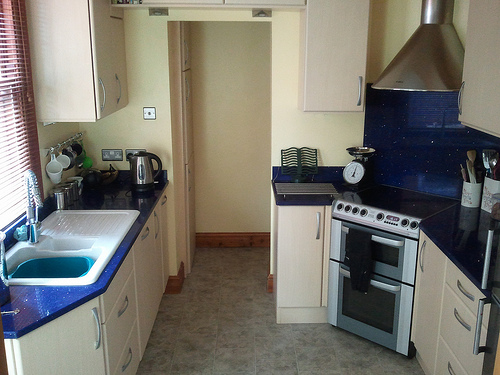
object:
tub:
[4, 255, 95, 279]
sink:
[0, 208, 143, 340]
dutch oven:
[328, 179, 464, 360]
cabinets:
[24, 0, 128, 127]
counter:
[0, 170, 169, 374]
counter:
[271, 165, 499, 375]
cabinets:
[300, 1, 372, 113]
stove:
[330, 185, 461, 240]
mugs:
[461, 176, 497, 213]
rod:
[43, 132, 84, 157]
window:
[0, 0, 47, 245]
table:
[275, 183, 339, 201]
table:
[419, 199, 500, 305]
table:
[0, 169, 168, 374]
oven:
[325, 181, 461, 358]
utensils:
[480, 149, 499, 182]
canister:
[461, 180, 482, 207]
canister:
[480, 175, 499, 215]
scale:
[343, 146, 376, 193]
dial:
[346, 146, 376, 158]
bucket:
[0, 241, 109, 285]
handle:
[315, 211, 320, 239]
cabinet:
[276, 205, 324, 307]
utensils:
[460, 151, 483, 185]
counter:
[410, 201, 499, 375]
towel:
[343, 228, 376, 295]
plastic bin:
[7, 256, 97, 278]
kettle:
[126, 150, 163, 195]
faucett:
[24, 169, 43, 244]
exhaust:
[369, 24, 466, 92]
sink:
[39, 236, 100, 251]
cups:
[45, 151, 70, 184]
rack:
[43, 131, 85, 158]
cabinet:
[0, 209, 141, 374]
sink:
[0, 209, 139, 287]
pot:
[126, 151, 163, 195]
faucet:
[14, 169, 44, 245]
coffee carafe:
[126, 151, 162, 192]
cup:
[56, 147, 71, 170]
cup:
[46, 147, 63, 184]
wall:
[34, 120, 95, 192]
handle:
[144, 152, 163, 180]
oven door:
[329, 217, 418, 286]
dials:
[332, 183, 461, 240]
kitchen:
[0, 0, 499, 374]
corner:
[270, 149, 500, 239]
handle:
[92, 307, 101, 350]